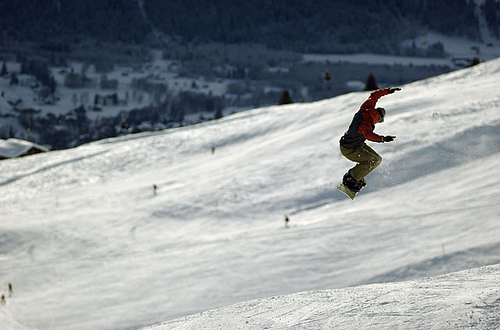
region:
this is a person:
[315, 75, 410, 196]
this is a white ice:
[147, 265, 297, 328]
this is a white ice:
[390, 181, 473, 238]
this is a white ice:
[25, 155, 146, 247]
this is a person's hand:
[360, 120, 398, 145]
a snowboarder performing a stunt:
[331, 84, 404, 200]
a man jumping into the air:
[332, 84, 403, 200]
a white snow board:
[332, 179, 359, 201]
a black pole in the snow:
[208, 140, 217, 153]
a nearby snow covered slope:
[128, 261, 498, 327]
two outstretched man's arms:
[369, 85, 401, 143]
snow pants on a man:
[338, 136, 384, 191]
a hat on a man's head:
[378, 107, 388, 122]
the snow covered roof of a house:
[1, 139, 47, 157]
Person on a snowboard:
[331, 84, 405, 205]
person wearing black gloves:
[386, 85, 401, 98]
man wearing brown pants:
[333, 133, 381, 175]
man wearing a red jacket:
[328, 83, 384, 146]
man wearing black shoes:
[346, 170, 365, 190]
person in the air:
[334, 77, 398, 208]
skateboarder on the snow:
[305, 61, 419, 218]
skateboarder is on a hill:
[150, 43, 494, 314]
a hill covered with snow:
[5, 55, 496, 328]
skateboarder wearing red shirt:
[323, 72, 410, 198]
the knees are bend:
[347, 142, 389, 177]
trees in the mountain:
[0, 5, 468, 93]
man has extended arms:
[331, 68, 408, 206]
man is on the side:
[330, 69, 408, 206]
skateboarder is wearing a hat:
[318, 62, 422, 202]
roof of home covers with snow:
[1, 116, 56, 173]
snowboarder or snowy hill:
[338, 63, 395, 208]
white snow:
[174, 268, 222, 299]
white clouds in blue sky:
[54, 23, 82, 43]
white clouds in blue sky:
[218, 38, 240, 65]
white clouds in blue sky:
[292, 12, 312, 29]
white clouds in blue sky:
[387, 8, 431, 59]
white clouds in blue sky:
[428, 1, 455, 36]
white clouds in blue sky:
[295, 21, 342, 68]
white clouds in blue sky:
[197, 39, 244, 100]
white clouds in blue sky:
[128, 3, 155, 35]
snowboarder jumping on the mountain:
[337, 77, 416, 191]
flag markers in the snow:
[3, 130, 296, 314]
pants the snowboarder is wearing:
[344, 145, 379, 180]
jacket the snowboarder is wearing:
[337, 85, 386, 144]